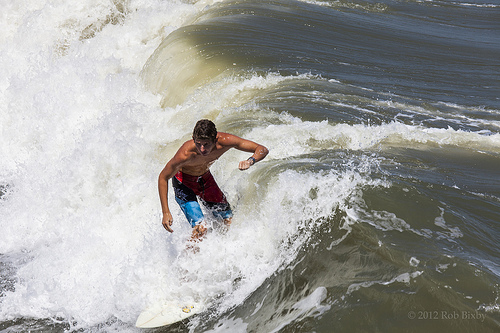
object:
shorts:
[172, 170, 233, 228]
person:
[158, 119, 269, 252]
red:
[175, 171, 227, 204]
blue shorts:
[174, 188, 232, 229]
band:
[247, 157, 255, 165]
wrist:
[246, 159, 255, 166]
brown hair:
[192, 119, 217, 143]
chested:
[178, 144, 228, 177]